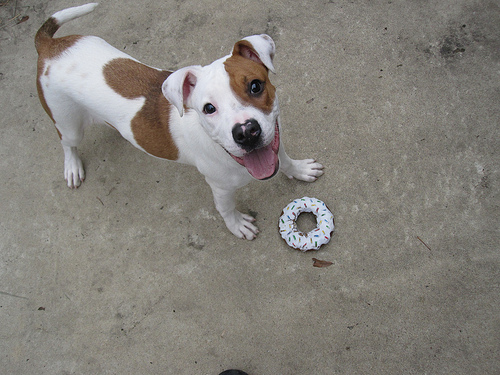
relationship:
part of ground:
[95, 262, 229, 353] [136, 282, 267, 372]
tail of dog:
[28, 4, 103, 53] [20, 6, 352, 226]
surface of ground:
[128, 260, 271, 340] [108, 262, 257, 353]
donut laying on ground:
[274, 178, 338, 259] [269, 184, 368, 273]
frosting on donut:
[270, 186, 344, 262] [265, 189, 355, 277]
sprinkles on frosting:
[270, 185, 353, 269] [269, 193, 347, 253]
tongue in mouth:
[219, 135, 322, 192] [207, 109, 344, 200]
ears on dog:
[149, 34, 318, 107] [130, 19, 335, 209]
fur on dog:
[79, 67, 149, 127] [20, 6, 352, 226]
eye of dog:
[190, 75, 284, 132] [35, 8, 382, 228]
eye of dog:
[192, 95, 227, 129] [45, 27, 335, 217]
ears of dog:
[156, 64, 198, 118] [46, 7, 397, 252]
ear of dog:
[222, 27, 290, 64] [26, 5, 406, 264]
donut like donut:
[276, 193, 337, 254] [276, 193, 337, 254]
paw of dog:
[220, 201, 273, 258] [55, 3, 385, 270]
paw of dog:
[286, 135, 326, 205] [40, 20, 410, 260]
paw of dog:
[43, 141, 98, 219] [23, 1, 363, 241]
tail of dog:
[22, 4, 140, 69] [32, 16, 381, 253]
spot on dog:
[82, 39, 155, 149] [35, 8, 382, 228]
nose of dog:
[227, 117, 282, 159] [35, 8, 382, 228]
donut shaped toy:
[276, 193, 337, 254] [267, 185, 359, 263]